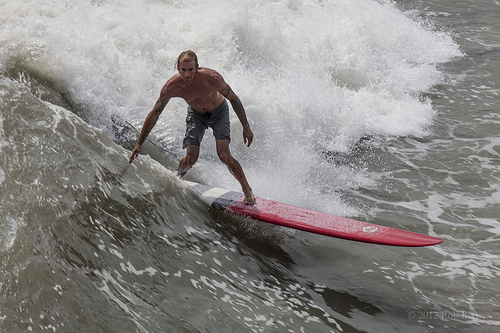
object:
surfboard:
[179, 178, 443, 256]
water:
[1, 1, 498, 331]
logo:
[362, 226, 379, 235]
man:
[128, 50, 257, 206]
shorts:
[181, 100, 232, 150]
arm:
[207, 76, 254, 130]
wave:
[0, 2, 468, 332]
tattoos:
[219, 83, 251, 126]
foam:
[0, 0, 463, 195]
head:
[176, 50, 200, 86]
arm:
[136, 93, 171, 147]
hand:
[241, 124, 258, 148]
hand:
[127, 146, 140, 166]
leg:
[209, 125, 260, 206]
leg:
[171, 125, 208, 179]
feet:
[242, 191, 260, 205]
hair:
[177, 51, 199, 65]